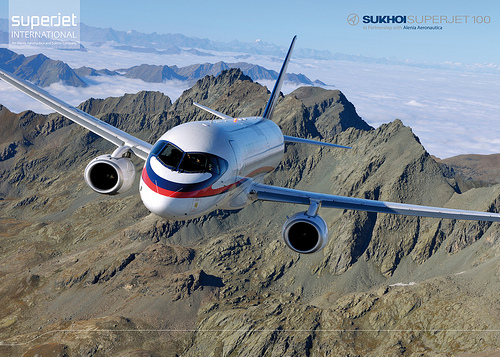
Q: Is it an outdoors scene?
A: Yes, it is outdoors.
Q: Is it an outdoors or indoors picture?
A: It is outdoors.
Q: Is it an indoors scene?
A: No, it is outdoors.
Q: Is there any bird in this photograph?
A: No, there are no birds.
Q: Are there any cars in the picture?
A: No, there are no cars.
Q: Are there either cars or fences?
A: No, there are no cars or fences.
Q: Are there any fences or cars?
A: No, there are no cars or fences.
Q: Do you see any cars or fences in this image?
A: No, there are no cars or fences.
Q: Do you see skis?
A: No, there are no skis.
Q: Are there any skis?
A: No, there are no skis.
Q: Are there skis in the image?
A: No, there are no skis.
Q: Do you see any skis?
A: No, there are no skis.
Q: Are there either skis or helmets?
A: No, there are no skis or helmets.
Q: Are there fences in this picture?
A: No, there are no fences.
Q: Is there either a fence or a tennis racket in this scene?
A: No, there are no fences or rackets.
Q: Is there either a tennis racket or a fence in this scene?
A: No, there are no fences or rackets.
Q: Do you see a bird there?
A: No, there are no birds.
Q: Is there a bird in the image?
A: No, there are no birds.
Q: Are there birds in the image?
A: No, there are no birds.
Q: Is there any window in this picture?
A: Yes, there is a window.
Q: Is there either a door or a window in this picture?
A: Yes, there is a window.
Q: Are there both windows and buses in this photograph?
A: No, there is a window but no buses.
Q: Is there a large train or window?
A: Yes, there is a large window.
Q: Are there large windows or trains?
A: Yes, there is a large window.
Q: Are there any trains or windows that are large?
A: Yes, the window is large.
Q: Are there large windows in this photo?
A: Yes, there is a large window.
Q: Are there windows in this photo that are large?
A: Yes, there is a large window.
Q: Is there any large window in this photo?
A: Yes, there is a large window.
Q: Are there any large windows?
A: Yes, there is a large window.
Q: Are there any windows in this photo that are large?
A: Yes, there is a window that is large.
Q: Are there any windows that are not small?
A: Yes, there is a large window.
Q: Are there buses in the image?
A: No, there are no buses.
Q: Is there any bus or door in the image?
A: No, there are no buses or doors.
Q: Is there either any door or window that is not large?
A: No, there is a window but it is large.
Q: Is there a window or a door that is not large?
A: No, there is a window but it is large.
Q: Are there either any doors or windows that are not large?
A: No, there is a window but it is large.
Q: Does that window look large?
A: Yes, the window is large.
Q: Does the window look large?
A: Yes, the window is large.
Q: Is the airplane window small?
A: No, the window is large.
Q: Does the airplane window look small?
A: No, the window is large.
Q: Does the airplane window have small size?
A: No, the window is large.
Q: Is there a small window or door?
A: No, there is a window but it is large.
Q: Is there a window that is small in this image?
A: No, there is a window but it is large.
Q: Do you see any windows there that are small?
A: No, there is a window but it is large.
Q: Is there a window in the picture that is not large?
A: No, there is a window but it is large.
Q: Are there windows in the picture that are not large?
A: No, there is a window but it is large.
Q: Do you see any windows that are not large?
A: No, there is a window but it is large.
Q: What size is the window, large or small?
A: The window is large.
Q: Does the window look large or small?
A: The window is large.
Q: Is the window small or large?
A: The window is large.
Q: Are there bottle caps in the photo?
A: No, there are no bottle caps.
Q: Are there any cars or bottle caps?
A: No, there are no bottle caps or cars.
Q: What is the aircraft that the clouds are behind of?
A: The aircraft is an airplane.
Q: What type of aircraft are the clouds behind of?
A: The clouds are behind the airplane.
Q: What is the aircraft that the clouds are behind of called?
A: The aircraft is an airplane.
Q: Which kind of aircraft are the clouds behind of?
A: The clouds are behind the airplane.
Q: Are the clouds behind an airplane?
A: Yes, the clouds are behind an airplane.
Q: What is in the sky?
A: The clouds are in the sky.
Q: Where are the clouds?
A: The clouds are in the sky.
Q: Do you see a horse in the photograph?
A: No, there are no horses.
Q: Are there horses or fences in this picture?
A: No, there are no horses or fences.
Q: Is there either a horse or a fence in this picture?
A: No, there are no horses or fences.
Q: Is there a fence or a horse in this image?
A: No, there are no horses or fences.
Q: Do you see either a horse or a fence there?
A: No, there are no horses or fences.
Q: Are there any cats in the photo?
A: No, there are no cats.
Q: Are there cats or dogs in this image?
A: No, there are no cats or dogs.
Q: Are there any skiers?
A: No, there are no skiers.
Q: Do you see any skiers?
A: No, there are no skiers.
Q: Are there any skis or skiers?
A: No, there are no skiers or skis.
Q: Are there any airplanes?
A: Yes, there is an airplane.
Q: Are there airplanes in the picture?
A: Yes, there is an airplane.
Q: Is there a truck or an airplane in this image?
A: Yes, there is an airplane.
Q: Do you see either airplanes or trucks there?
A: Yes, there is an airplane.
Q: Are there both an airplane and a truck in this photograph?
A: No, there is an airplane but no trucks.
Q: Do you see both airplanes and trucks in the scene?
A: No, there is an airplane but no trucks.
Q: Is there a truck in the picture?
A: No, there are no trucks.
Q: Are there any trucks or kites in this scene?
A: No, there are no trucks or kites.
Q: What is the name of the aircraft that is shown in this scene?
A: The aircraft is an airplane.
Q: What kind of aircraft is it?
A: The aircraft is an airplane.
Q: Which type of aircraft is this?
A: This is an airplane.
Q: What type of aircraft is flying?
A: The aircraft is an airplane.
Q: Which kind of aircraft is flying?
A: The aircraft is an airplane.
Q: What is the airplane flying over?
A: The airplane is flying over the mountain.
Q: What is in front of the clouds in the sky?
A: The airplane is in front of the clouds.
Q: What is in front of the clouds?
A: The airplane is in front of the clouds.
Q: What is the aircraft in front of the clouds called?
A: The aircraft is an airplane.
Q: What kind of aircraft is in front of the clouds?
A: The aircraft is an airplane.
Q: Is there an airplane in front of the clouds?
A: Yes, there is an airplane in front of the clouds.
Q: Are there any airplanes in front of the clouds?
A: Yes, there is an airplane in front of the clouds.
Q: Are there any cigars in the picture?
A: No, there are no cigars.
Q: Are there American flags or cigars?
A: No, there are no cigars or American flags.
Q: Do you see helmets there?
A: No, there are no helmets.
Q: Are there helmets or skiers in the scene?
A: No, there are no helmets or skiers.